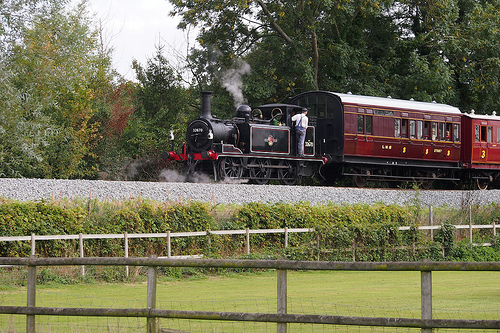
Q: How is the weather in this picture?
A: It is overcast.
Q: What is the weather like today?
A: It is overcast.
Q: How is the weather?
A: It is overcast.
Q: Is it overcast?
A: Yes, it is overcast.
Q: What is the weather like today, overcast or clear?
A: It is overcast.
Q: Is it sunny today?
A: No, it is overcast.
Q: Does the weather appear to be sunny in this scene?
A: No, it is overcast.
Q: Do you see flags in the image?
A: No, there are no flags.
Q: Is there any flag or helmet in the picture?
A: No, there are no flags or helmets.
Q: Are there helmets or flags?
A: No, there are no flags or helmets.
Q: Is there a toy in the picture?
A: No, there are no toys.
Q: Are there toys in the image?
A: No, there are no toys.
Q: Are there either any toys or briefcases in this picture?
A: No, there are no toys or briefcases.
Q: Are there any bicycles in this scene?
A: No, there are no bicycles.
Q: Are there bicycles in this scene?
A: No, there are no bicycles.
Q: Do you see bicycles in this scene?
A: No, there are no bicycles.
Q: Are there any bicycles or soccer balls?
A: No, there are no bicycles or soccer balls.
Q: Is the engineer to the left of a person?
A: Yes, the engineer is to the left of a person.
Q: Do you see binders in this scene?
A: No, there are no binders.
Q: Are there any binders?
A: No, there are no binders.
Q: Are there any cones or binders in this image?
A: No, there are no binders or cones.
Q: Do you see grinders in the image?
A: No, there are no grinders.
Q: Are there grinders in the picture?
A: No, there are no grinders.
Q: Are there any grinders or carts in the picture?
A: No, there are no grinders or carts.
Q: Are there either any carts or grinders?
A: No, there are no grinders or carts.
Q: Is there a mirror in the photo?
A: No, there are no mirrors.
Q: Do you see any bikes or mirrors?
A: No, there are no mirrors or bikes.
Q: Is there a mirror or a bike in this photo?
A: No, there are no mirrors or bikes.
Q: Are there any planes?
A: No, there are no planes.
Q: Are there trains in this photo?
A: Yes, there is a train.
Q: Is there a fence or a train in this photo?
A: Yes, there is a train.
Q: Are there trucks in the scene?
A: No, there are no trucks.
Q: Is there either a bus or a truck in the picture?
A: No, there are no trucks or buses.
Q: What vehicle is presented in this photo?
A: The vehicle is a train.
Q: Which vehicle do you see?
A: The vehicle is a train.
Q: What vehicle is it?
A: The vehicle is a train.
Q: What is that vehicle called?
A: That is a train.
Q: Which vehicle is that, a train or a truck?
A: That is a train.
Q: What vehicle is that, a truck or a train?
A: That is a train.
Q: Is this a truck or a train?
A: This is a train.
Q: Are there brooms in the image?
A: No, there are no brooms.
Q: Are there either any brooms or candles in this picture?
A: No, there are no brooms or candles.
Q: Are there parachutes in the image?
A: No, there are no parachutes.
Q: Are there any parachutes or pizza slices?
A: No, there are no parachutes or pizza slices.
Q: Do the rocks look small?
A: Yes, the rocks are small.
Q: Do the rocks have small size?
A: Yes, the rocks are small.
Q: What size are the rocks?
A: The rocks are small.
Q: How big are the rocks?
A: The rocks are small.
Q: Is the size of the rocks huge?
A: No, the rocks are small.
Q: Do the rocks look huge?
A: No, the rocks are small.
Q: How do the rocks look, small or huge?
A: The rocks are small.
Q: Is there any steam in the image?
A: Yes, there is steam.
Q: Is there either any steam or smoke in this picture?
A: Yes, there is steam.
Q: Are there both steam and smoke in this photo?
A: Yes, there are both steam and smoke.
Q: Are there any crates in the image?
A: No, there are no crates.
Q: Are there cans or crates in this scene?
A: No, there are no crates or cans.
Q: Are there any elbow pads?
A: No, there are no elbow pads.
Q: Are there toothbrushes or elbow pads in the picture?
A: No, there are no elbow pads or toothbrushes.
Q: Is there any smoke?
A: Yes, there is smoke.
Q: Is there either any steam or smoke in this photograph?
A: Yes, there is smoke.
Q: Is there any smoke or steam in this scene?
A: Yes, there is smoke.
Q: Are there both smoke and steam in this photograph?
A: Yes, there are both smoke and steam.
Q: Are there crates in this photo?
A: No, there are no crates.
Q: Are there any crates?
A: No, there are no crates.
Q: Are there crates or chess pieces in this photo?
A: No, there are no crates or chess pieces.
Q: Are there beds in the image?
A: Yes, there is a bed.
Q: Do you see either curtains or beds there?
A: Yes, there is a bed.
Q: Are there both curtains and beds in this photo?
A: No, there is a bed but no curtains.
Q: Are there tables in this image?
A: No, there are no tables.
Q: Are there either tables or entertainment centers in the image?
A: No, there are no tables or entertainment centers.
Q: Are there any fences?
A: Yes, there is a fence.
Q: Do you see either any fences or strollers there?
A: Yes, there is a fence.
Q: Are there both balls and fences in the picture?
A: No, there is a fence but no balls.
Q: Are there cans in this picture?
A: No, there are no cans.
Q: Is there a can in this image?
A: No, there are no cans.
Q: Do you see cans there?
A: No, there are no cans.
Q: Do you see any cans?
A: No, there are no cans.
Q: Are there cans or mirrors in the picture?
A: No, there are no cans or mirrors.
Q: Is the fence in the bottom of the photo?
A: Yes, the fence is in the bottom of the image.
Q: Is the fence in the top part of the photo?
A: No, the fence is in the bottom of the image.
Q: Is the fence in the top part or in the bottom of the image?
A: The fence is in the bottom of the image.